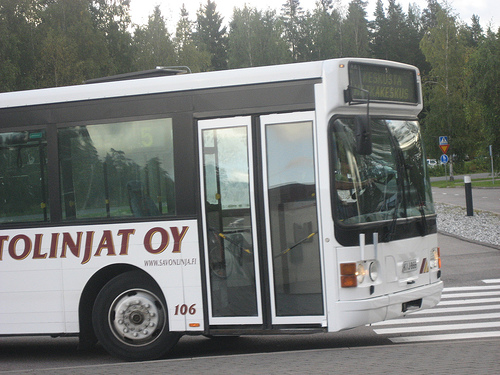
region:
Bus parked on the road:
[90, 43, 453, 351]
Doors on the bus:
[194, 132, 326, 321]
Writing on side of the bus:
[7, 228, 191, 280]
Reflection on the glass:
[86, 120, 172, 193]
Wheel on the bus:
[93, 275, 204, 366]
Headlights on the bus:
[341, 240, 388, 287]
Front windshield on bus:
[325, 106, 437, 219]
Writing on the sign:
[310, 44, 442, 116]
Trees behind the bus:
[36, 30, 266, 76]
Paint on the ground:
[438, 276, 483, 331]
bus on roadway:
[2, 72, 463, 352]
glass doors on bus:
[181, 100, 427, 335]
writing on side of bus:
[0, 116, 198, 338]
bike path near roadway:
[426, 161, 499, 368]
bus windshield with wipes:
[324, 113, 444, 246]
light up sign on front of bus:
[338, 58, 452, 317]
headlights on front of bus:
[331, 237, 446, 303]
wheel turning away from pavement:
[81, 268, 176, 358]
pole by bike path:
[436, 169, 499, 230]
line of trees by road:
[4, 5, 499, 172]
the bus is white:
[47, 34, 483, 365]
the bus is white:
[36, 71, 381, 128]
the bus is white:
[306, 195, 471, 329]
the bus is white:
[12, 215, 173, 350]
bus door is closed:
[153, 97, 369, 354]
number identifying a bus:
[173, 303, 198, 317]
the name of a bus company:
[0, 225, 198, 269]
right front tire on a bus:
[92, 269, 181, 364]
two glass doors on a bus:
[196, 107, 328, 325]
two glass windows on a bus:
[0, 113, 174, 223]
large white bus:
[1, 56, 453, 357]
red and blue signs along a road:
[435, 135, 451, 185]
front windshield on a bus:
[326, 114, 439, 226]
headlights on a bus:
[354, 260, 381, 285]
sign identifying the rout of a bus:
[346, 60, 419, 105]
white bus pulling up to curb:
[1, 55, 443, 359]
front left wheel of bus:
[87, 270, 167, 360]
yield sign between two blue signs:
[436, 133, 451, 167]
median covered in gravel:
[433, 197, 498, 248]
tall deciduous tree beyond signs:
[421, 3, 472, 159]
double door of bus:
[196, 109, 329, 327]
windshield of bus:
[328, 112, 436, 226]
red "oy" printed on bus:
[141, 226, 192, 258]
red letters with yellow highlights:
[0, 224, 192, 266]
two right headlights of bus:
[356, 260, 381, 283]